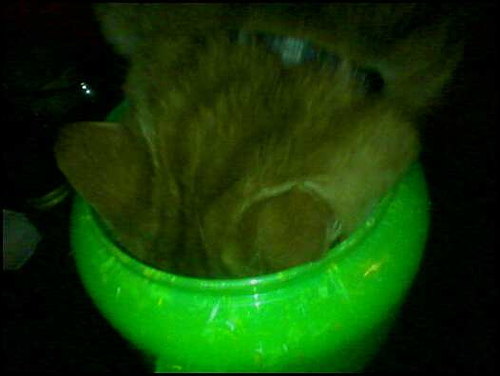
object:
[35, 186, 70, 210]
gold lid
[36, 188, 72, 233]
jar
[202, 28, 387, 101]
collar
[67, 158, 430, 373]
vase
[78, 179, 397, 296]
rim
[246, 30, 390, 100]
clip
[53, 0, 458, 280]
cat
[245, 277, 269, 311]
reflection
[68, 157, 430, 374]
bowl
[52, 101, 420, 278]
cats head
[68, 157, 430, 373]
dish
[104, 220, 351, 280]
cat's face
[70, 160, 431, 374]
jar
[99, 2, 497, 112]
body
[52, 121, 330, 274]
cat's ears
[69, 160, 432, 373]
pot